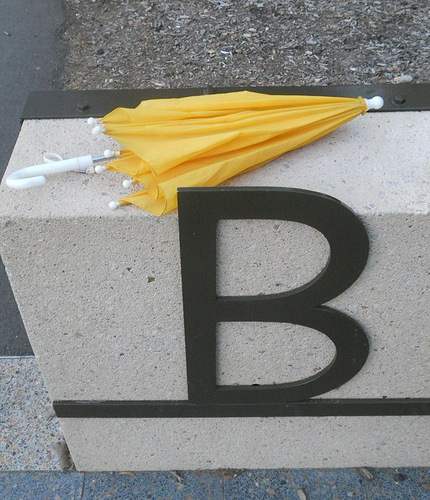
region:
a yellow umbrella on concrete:
[2, 86, 387, 219]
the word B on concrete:
[174, 160, 370, 399]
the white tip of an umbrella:
[108, 200, 118, 212]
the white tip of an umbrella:
[121, 178, 131, 189]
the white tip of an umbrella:
[94, 164, 108, 176]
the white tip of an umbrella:
[101, 148, 116, 159]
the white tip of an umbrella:
[84, 117, 97, 124]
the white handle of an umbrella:
[5, 152, 94, 188]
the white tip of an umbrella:
[364, 93, 387, 114]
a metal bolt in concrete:
[76, 100, 88, 112]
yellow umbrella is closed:
[77, 93, 393, 196]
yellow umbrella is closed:
[89, 87, 367, 220]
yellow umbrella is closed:
[86, 89, 380, 192]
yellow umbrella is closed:
[74, 90, 387, 220]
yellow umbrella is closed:
[63, 79, 333, 170]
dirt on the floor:
[92, 474, 357, 499]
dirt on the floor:
[90, 465, 298, 495]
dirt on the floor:
[118, 469, 232, 493]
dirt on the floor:
[98, 452, 349, 497]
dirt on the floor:
[89, 455, 260, 493]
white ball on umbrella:
[85, 115, 97, 126]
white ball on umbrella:
[93, 124, 102, 132]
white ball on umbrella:
[101, 148, 113, 158]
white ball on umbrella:
[93, 165, 102, 175]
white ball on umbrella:
[121, 178, 130, 187]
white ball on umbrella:
[108, 199, 118, 209]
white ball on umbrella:
[372, 93, 385, 110]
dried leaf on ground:
[295, 485, 307, 498]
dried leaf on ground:
[357, 464, 374, 480]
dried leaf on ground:
[169, 468, 186, 485]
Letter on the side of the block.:
[144, 179, 375, 401]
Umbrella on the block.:
[4, 56, 403, 223]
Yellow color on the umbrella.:
[4, 78, 391, 216]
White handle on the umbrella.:
[3, 150, 95, 194]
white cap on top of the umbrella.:
[356, 86, 386, 117]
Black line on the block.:
[50, 391, 427, 421]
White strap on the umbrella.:
[37, 150, 65, 164]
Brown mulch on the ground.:
[65, 4, 428, 91]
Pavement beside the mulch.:
[1, 3, 59, 182]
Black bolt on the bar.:
[388, 90, 408, 109]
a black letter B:
[157, 165, 386, 445]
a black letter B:
[154, 167, 376, 447]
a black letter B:
[166, 182, 370, 449]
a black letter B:
[170, 176, 372, 410]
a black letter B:
[159, 169, 383, 436]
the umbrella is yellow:
[53, 71, 370, 223]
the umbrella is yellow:
[71, 67, 343, 241]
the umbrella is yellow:
[101, 75, 395, 218]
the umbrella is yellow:
[81, 68, 387, 271]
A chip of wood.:
[357, 462, 376, 481]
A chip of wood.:
[392, 470, 401, 482]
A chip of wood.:
[169, 468, 182, 479]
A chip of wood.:
[169, 476, 178, 482]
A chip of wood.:
[392, 69, 412, 83]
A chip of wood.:
[371, 60, 386, 73]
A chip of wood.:
[277, 36, 304, 51]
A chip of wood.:
[143, 77, 165, 91]